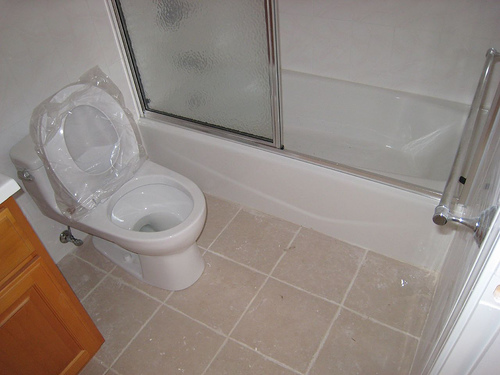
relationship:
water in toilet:
[132, 214, 172, 237] [9, 66, 210, 293]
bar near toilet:
[432, 48, 497, 250] [9, 66, 210, 293]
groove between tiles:
[267, 274, 341, 308] [229, 226, 367, 374]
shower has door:
[106, 2, 498, 278] [109, 2, 284, 151]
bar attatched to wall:
[432, 48, 497, 250] [416, 120, 499, 374]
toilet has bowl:
[9, 66, 210, 293] [81, 160, 205, 295]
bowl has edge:
[81, 160, 205, 295] [84, 161, 203, 243]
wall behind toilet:
[1, 1, 138, 265] [9, 66, 210, 293]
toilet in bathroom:
[9, 66, 210, 293] [1, 3, 500, 374]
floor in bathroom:
[54, 191, 435, 374] [1, 3, 500, 374]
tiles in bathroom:
[229, 226, 367, 374] [1, 3, 500, 374]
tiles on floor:
[229, 226, 367, 374] [54, 191, 435, 374]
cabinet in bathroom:
[1, 198, 105, 374] [1, 3, 500, 374]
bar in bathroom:
[432, 48, 497, 250] [1, 3, 500, 374]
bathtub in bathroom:
[137, 73, 487, 280] [1, 3, 500, 374]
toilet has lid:
[9, 66, 210, 293] [42, 85, 142, 208]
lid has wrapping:
[42, 85, 142, 208] [30, 65, 150, 223]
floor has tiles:
[54, 191, 435, 374] [229, 226, 367, 374]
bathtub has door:
[137, 73, 487, 280] [109, 2, 284, 151]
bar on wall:
[432, 48, 497, 250] [416, 120, 499, 374]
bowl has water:
[81, 160, 205, 295] [132, 214, 172, 237]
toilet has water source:
[9, 66, 210, 293] [12, 134, 71, 225]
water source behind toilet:
[12, 134, 71, 225] [9, 66, 210, 293]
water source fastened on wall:
[12, 134, 71, 225] [1, 1, 138, 265]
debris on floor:
[399, 276, 407, 288] [54, 191, 435, 374]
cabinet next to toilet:
[1, 198, 105, 374] [9, 66, 210, 293]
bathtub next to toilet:
[137, 73, 487, 280] [9, 66, 210, 293]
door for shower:
[109, 2, 284, 151] [106, 2, 498, 278]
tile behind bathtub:
[275, 0, 500, 112] [137, 73, 487, 280]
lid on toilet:
[42, 85, 142, 208] [9, 66, 210, 293]